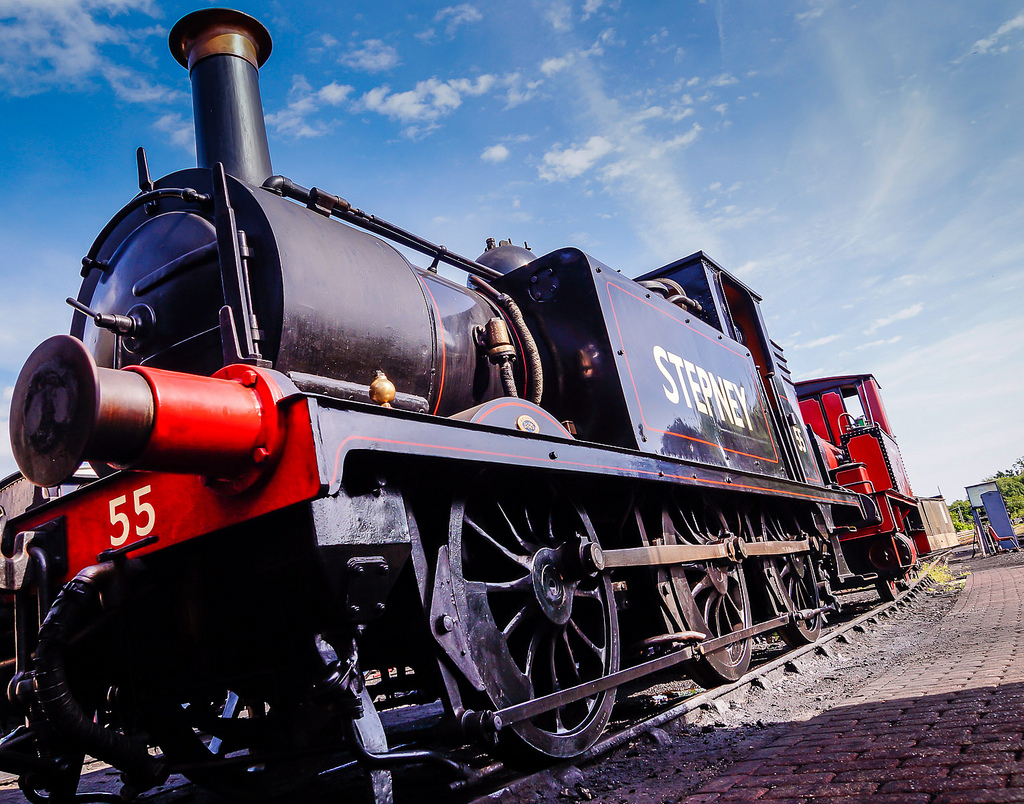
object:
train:
[9, 11, 931, 792]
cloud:
[310, 26, 393, 74]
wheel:
[640, 495, 764, 688]